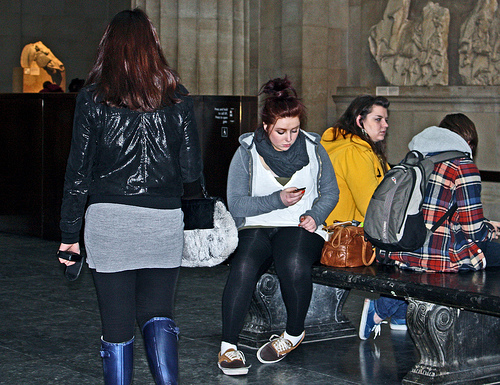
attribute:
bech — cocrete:
[224, 254, 499, 384]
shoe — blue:
[143, 317, 181, 384]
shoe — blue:
[99, 336, 135, 381]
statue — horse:
[21, 43, 67, 73]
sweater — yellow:
[323, 128, 390, 232]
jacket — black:
[60, 76, 202, 243]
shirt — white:
[250, 133, 324, 228]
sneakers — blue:
[215, 332, 307, 375]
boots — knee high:
[104, 314, 181, 383]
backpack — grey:
[372, 150, 442, 270]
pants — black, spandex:
[200, 200, 342, 347]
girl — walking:
[58, 6, 203, 378]